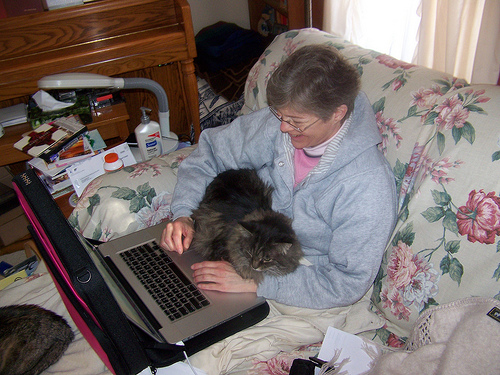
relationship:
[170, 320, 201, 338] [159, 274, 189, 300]
silver and black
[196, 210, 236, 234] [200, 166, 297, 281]
long haired cat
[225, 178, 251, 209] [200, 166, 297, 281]
dark haired cat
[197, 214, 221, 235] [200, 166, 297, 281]
gray haired cat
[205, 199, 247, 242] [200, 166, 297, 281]
fluffy haired cat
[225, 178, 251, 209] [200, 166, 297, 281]
dark fluffy cat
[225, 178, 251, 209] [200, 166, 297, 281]
dark gray cat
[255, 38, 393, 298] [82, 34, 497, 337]
woman on sofa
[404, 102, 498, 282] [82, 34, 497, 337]
flower print sofa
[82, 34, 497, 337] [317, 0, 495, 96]
sofa by window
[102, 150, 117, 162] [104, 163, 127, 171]
red and white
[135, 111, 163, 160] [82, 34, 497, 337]
bottle beside sofa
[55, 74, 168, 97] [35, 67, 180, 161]
gray table lamp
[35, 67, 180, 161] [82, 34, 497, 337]
lamp near sofa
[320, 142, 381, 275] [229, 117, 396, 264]
gray hooded shirt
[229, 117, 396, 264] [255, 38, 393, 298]
shirt on lady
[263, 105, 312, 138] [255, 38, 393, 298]
glasses on woman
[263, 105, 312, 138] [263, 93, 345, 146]
glasses on face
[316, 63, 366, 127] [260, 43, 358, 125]
short gray hair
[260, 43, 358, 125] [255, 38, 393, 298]
hair on woman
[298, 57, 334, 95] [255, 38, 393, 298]
gray haired woman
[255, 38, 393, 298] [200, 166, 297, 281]
woman and cat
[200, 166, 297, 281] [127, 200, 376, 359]
cat in lap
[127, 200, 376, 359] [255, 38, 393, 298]
lap of woman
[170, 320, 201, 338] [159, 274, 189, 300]
grey and black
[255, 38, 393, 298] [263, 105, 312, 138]
lady wearing eyeglass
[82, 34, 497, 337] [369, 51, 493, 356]
sofa has cover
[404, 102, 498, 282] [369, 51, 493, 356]
floral printed cover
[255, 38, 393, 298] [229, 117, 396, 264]
woman wears coat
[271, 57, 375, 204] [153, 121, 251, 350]
elderly lady working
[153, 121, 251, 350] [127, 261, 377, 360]
working on lap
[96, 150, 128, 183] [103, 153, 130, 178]
bottle of tylenol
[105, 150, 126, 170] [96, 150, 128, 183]
one large bottle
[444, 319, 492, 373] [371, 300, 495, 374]
cream color throw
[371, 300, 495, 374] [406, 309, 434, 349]
throw has lace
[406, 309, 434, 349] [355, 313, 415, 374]
lace on edge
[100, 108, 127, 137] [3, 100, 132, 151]
wooden piano bench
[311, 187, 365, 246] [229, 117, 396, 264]
blue hoodie jacket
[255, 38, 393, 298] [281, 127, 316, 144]
woman with smile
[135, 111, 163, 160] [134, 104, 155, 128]
bottle with pump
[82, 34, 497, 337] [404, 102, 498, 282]
sofa with flowers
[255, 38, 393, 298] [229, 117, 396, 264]
woman with hoodie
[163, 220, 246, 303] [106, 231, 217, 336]
hands near keyboard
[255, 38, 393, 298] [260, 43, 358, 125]
woman doesnt color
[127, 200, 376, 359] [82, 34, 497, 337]
sitting on couch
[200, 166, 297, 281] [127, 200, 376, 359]
cat on lap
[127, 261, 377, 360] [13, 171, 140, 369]
lap in case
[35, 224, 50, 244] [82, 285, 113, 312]
pink and black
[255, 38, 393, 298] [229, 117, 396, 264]
woman wearing hoodie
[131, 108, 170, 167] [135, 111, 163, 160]
jar of lotion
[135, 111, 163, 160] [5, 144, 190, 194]
lotion on table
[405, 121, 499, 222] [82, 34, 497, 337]
flowers on couch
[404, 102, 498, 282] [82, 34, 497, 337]
flower covered couch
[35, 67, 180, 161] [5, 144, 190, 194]
lamp on table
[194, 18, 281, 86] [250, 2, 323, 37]
duffle behind cabinet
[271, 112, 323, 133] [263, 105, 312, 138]
silver framed eyeglasses